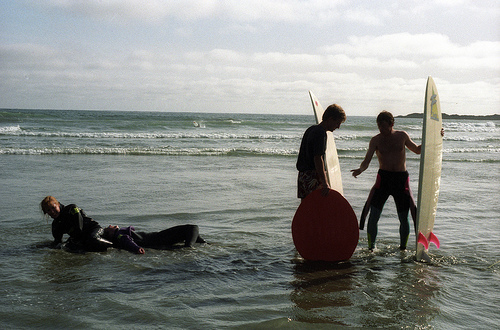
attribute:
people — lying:
[28, 182, 210, 281]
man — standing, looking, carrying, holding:
[295, 101, 332, 172]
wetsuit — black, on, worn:
[53, 206, 123, 271]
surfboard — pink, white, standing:
[413, 85, 440, 186]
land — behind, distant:
[398, 103, 494, 130]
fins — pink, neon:
[408, 222, 444, 262]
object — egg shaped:
[288, 181, 368, 245]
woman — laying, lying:
[99, 211, 192, 271]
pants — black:
[366, 176, 418, 235]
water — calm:
[121, 137, 222, 195]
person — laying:
[100, 211, 235, 264]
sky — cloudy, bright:
[84, 13, 251, 110]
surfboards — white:
[282, 72, 493, 223]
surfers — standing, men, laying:
[252, 105, 377, 199]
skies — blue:
[130, 16, 350, 111]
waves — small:
[86, 115, 174, 147]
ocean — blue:
[81, 103, 166, 120]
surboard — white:
[301, 88, 388, 204]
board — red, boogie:
[281, 184, 373, 251]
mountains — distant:
[397, 105, 497, 138]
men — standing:
[290, 96, 435, 200]